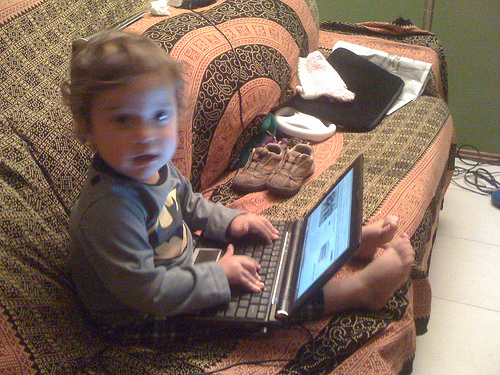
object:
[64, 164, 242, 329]
shirt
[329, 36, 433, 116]
pillow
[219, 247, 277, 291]
keys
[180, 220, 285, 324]
keyboard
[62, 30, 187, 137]
hair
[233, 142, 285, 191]
shoe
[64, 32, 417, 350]
boy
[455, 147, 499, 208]
cords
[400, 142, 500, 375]
floor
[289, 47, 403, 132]
case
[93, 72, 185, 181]
face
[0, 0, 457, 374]
couch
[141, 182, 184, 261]
logo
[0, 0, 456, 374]
cover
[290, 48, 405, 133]
black laptop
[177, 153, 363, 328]
laptop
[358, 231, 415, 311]
feet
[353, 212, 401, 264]
feet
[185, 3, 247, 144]
power cord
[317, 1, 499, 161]
wall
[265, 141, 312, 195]
shoe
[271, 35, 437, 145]
cover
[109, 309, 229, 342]
pants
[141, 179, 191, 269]
symbol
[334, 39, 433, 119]
newspaper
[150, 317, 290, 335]
lap